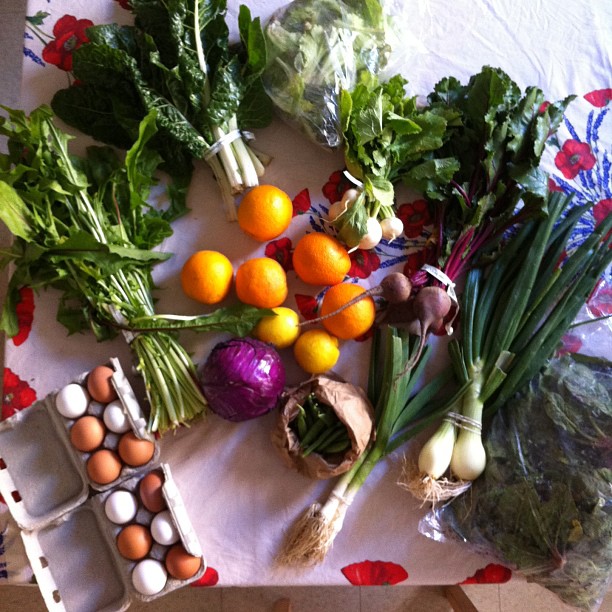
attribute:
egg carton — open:
[19, 463, 204, 611]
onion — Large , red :
[198, 333, 281, 422]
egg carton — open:
[0, 353, 161, 533]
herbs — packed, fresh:
[416, 354, 610, 611]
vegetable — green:
[295, 66, 573, 378]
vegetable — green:
[308, 68, 460, 255]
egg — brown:
[163, 541, 203, 580]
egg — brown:
[114, 524, 151, 560]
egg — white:
[150, 512, 178, 546]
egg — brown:
[139, 473, 164, 512]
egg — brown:
[68, 414, 105, 450]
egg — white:
[103, 488, 137, 524]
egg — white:
[131, 558, 168, 595]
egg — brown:
[164, 545, 201, 579]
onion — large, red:
[195, 334, 287, 421]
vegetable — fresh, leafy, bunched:
[51, 3, 267, 222]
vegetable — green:
[401, 190, 611, 516]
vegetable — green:
[280, 326, 469, 567]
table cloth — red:
[0, 2, 611, 586]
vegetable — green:
[11, 191, 156, 314]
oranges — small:
[192, 200, 367, 371]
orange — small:
[232, 181, 300, 242]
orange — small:
[285, 229, 355, 292]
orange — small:
[321, 280, 377, 337]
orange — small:
[236, 255, 291, 310]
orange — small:
[177, 244, 239, 310]